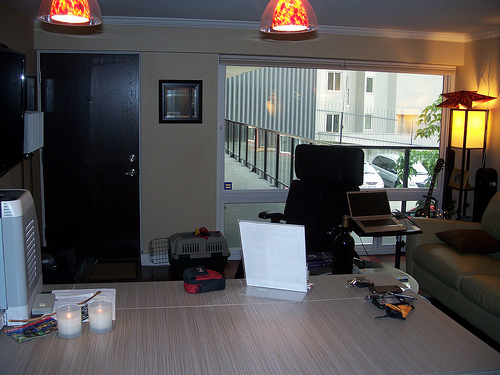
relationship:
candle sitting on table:
[56, 299, 82, 339] [1, 269, 499, 374]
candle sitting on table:
[86, 297, 114, 334] [1, 269, 499, 374]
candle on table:
[56, 299, 82, 339] [1, 269, 499, 374]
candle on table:
[86, 297, 114, 334] [1, 269, 499, 374]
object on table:
[366, 294, 416, 322] [1, 269, 499, 374]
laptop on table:
[346, 189, 406, 237] [346, 215, 424, 268]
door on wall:
[39, 51, 141, 281] [34, 21, 473, 284]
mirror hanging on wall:
[157, 78, 202, 126] [34, 21, 473, 284]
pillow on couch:
[434, 228, 498, 254] [403, 189, 499, 359]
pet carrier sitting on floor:
[148, 225, 231, 278] [43, 254, 408, 284]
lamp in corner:
[445, 107, 489, 220] [446, 43, 492, 222]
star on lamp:
[435, 90, 498, 111] [445, 107, 489, 220]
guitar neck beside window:
[418, 157, 444, 217] [223, 66, 449, 252]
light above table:
[33, 0, 104, 35] [1, 269, 499, 374]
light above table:
[257, 0, 320, 42] [1, 269, 499, 374]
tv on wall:
[1, 42, 25, 178] [1, 1, 43, 279]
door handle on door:
[123, 167, 136, 178] [39, 51, 141, 281]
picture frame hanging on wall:
[23, 74, 38, 110] [1, 1, 43, 279]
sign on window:
[223, 180, 234, 192] [223, 66, 449, 252]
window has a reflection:
[223, 66, 449, 252] [263, 90, 303, 115]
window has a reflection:
[223, 66, 449, 252] [392, 111, 427, 128]